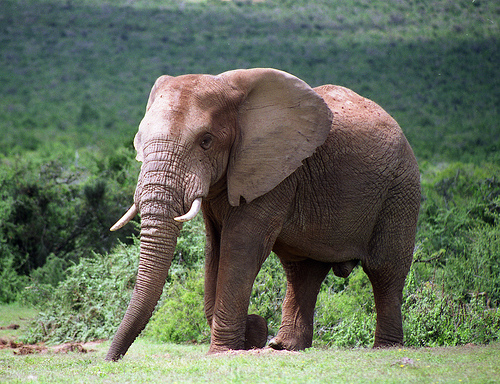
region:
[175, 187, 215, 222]
Elephant has white tusk.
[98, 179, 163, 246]
Elephant has white tusk.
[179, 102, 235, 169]
Elephant has large eye.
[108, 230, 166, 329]
Elephant has long gray trunk.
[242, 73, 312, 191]
Elephant has huge gray ear.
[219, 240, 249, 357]
Elephant has large gray leg.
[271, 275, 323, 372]
Elephant has large gray leg.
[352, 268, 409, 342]
Elephant has large gray leg.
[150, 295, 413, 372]
Elephant is walking thru grass.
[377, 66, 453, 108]
Many green trees in background.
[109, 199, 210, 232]
pair of elephant tusks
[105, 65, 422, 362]
a elephant walking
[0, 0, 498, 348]
large green field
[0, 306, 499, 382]
large patch of grass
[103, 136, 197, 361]
a elephant trunk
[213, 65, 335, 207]
an elephant ear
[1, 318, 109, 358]
some piles of dirt in the grass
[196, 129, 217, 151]
The elephant's eye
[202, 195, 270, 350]
elephant's bent leg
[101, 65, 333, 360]
elephant's large head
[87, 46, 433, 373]
grey elephant walking in green field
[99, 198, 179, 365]
grey elephant trunk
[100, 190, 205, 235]
two white elephant tusks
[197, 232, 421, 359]
four elephant legs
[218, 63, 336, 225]
one elephant ear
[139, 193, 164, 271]
wrinkles in elephant trunk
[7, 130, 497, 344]
green trees and brush bordering green field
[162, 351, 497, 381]
green grass covered field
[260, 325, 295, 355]
one elephant toenail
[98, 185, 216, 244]
tusks of elephant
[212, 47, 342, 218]
ear of elephant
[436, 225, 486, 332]
vegetation behind elephant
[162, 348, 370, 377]
short grass on which elephant is standing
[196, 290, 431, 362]
four legs of elephant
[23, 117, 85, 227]
green leaves on vegetation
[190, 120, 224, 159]
eye of elephant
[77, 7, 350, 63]
green hillside behind elephant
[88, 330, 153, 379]
trunk of elephant touching grass on ground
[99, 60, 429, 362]
THIS IS AN ELEPHANT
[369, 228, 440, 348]
the foot of an elephant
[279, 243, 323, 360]
the foot of an elephant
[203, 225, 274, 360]
the foot of an elephant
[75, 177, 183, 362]
the trunk of an elephan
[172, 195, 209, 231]
the task of an elephant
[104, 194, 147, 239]
the task of an elephant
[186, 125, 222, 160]
the eye of an elephant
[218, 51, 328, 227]
the earof an elephant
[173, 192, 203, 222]
the elephant has a tusk on his head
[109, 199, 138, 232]
the elephant has a tusk on his head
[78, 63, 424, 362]
the elephant is walking left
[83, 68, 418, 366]
the elephant is grey in color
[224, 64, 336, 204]
the elephant has large ears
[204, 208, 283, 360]
the elephant is taking one step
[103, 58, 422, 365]
the elephant is walking on the grass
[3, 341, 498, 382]
the grass is green in color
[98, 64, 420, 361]
a large grey elephant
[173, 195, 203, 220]
a large elephant tusk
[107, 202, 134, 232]
a large elephant tusk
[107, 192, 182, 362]
a large elephant trunk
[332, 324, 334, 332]
a leaf on a stem